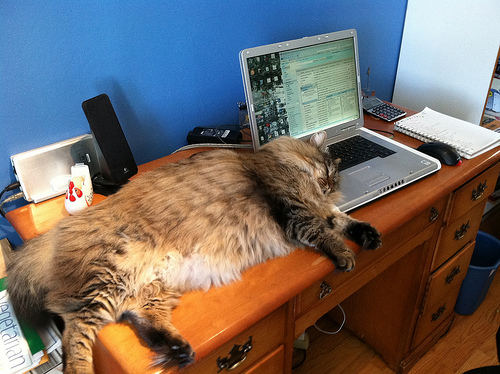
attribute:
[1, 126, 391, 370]
cat — large, longhair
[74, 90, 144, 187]
speaker — large, black and silver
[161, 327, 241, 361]
foot — back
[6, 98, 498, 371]
desk — wood, beautiful, large, brown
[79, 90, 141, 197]
speaker — black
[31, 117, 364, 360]
cat — really big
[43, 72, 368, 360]
cat — large, black and gray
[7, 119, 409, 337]
cat — big, fluffy, tabby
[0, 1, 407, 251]
wall — blue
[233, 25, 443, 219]
computer — black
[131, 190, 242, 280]
fur — long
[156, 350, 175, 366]
fur — long